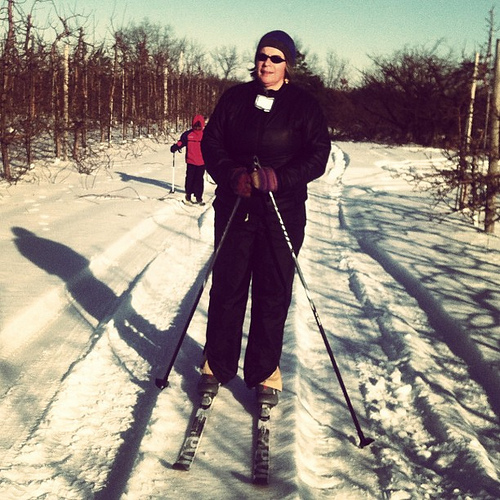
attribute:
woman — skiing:
[176, 26, 332, 396]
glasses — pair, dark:
[247, 43, 288, 69]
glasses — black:
[255, 49, 287, 66]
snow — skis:
[25, 202, 138, 318]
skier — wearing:
[168, 109, 227, 206]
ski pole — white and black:
[260, 181, 394, 473]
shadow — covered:
[8, 215, 208, 390]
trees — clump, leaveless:
[327, 38, 487, 143]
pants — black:
[210, 187, 307, 382]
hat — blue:
[263, 28, 303, 66]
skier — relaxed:
[198, 28, 334, 403]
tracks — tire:
[321, 195, 483, 498]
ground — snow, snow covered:
[1, 124, 498, 497]